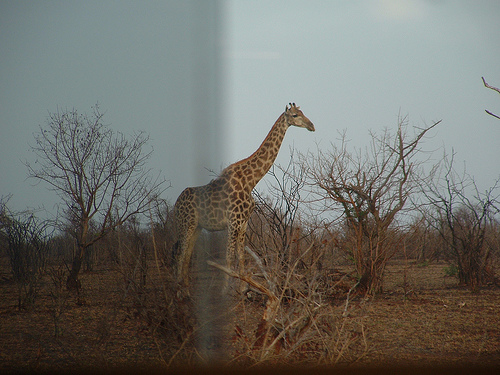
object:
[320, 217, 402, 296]
bushes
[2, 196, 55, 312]
bushes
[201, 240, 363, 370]
bushes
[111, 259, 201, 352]
bushes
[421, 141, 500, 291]
bushes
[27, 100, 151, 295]
tree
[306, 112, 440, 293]
tree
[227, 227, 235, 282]
leg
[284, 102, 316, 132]
head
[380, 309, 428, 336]
dirt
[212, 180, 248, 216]
pattern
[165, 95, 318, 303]
giraffe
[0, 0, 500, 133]
sky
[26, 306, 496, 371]
ground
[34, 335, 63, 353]
leaves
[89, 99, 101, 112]
leaves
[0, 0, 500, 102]
cloud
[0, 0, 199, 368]
window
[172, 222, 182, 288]
hind leg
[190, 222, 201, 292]
hind leg